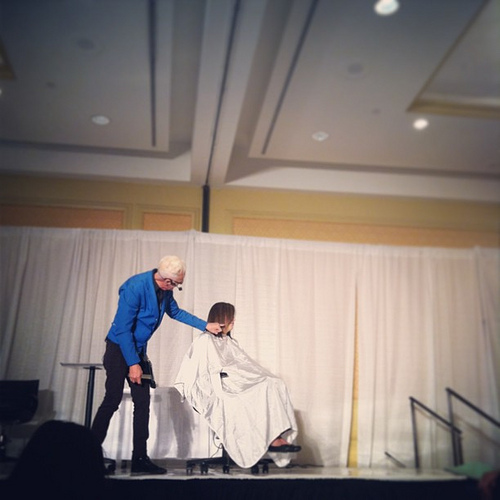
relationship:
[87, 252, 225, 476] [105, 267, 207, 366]
man wears sweater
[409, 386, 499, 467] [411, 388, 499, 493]
railing flank stairs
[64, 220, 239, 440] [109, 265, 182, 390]
man wearing cardigan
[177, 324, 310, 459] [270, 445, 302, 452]
cape under black shoes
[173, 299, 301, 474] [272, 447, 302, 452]
woman wearing black shoes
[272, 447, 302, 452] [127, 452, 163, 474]
black shoes wearing black shoes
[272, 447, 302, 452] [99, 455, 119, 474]
black shoes wearing black shoes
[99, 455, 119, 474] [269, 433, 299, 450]
black shoes on feet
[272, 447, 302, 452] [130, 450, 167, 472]
black shoes on feet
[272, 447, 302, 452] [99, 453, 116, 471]
black shoes on feet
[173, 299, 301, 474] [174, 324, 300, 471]
woman in cape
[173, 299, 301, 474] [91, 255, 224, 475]
woman with hairstylist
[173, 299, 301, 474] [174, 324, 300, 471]
woman wearing cape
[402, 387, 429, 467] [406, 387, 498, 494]
rails on stair case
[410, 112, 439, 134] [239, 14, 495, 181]
lights on ceiling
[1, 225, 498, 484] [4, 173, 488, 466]
white drapes camaflogue wall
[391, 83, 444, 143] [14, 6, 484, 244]
lights on ceiling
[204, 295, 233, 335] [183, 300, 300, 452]
hair on woman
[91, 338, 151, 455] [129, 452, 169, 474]
slacks with black shoes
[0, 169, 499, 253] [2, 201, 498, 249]
trim on wall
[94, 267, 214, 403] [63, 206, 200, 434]
sweater on barber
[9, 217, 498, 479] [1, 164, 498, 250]
white curtains in front of wall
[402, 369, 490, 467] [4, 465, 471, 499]
rails to back of stage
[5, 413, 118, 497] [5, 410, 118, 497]
audience member of audience member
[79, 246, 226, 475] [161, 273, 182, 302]
man wearing headset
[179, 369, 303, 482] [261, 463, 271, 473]
chair on wheel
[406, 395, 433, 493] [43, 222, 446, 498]
stairs on stage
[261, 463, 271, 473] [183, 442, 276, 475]
wheel on chair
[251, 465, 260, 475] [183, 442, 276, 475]
wheel on chair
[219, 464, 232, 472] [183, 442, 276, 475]
wheel on chair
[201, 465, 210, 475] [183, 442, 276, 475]
wheel on chair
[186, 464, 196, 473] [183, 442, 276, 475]
wheel on chair